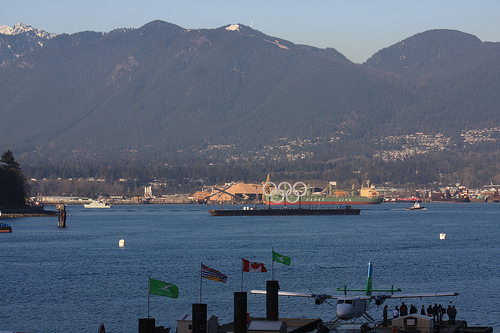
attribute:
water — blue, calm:
[0, 202, 499, 331]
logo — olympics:
[251, 171, 324, 224]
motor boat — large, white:
[84, 198, 112, 210]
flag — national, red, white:
[240, 258, 268, 274]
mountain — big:
[2, 22, 499, 179]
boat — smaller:
[385, 189, 439, 226]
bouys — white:
[434, 230, 449, 243]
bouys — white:
[112, 234, 130, 251]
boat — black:
[202, 174, 368, 227]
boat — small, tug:
[202, 181, 399, 279]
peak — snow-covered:
[3, 7, 56, 52]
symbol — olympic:
[256, 175, 308, 230]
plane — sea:
[252, 258, 459, 330]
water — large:
[149, 215, 343, 252]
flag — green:
[141, 267, 179, 302]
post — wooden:
[140, 319, 160, 329]